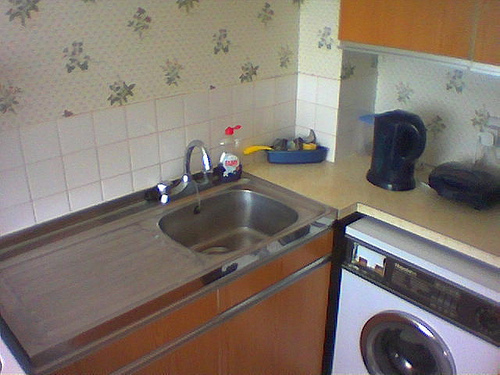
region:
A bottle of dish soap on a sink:
[220, 123, 243, 183]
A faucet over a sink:
[182, 138, 212, 177]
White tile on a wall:
[1, 72, 294, 237]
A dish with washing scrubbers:
[265, 140, 328, 161]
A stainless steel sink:
[149, 185, 314, 260]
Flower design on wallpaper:
[161, 57, 184, 89]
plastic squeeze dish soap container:
[218, 122, 241, 177]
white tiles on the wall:
[7, 72, 374, 237]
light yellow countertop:
[261, 144, 494, 263]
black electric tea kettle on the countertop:
[370, 106, 426, 189]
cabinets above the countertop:
[330, 2, 497, 66]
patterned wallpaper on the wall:
[4, 5, 499, 185]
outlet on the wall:
[467, 124, 497, 149]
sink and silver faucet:
[155, 141, 292, 251]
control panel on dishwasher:
[343, 239, 499, 335]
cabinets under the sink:
[33, 235, 343, 373]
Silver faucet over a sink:
[153, 135, 303, 261]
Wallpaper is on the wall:
[0, 0, 496, 175]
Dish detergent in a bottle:
[210, 120, 246, 185]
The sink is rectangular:
[150, 182, 300, 257]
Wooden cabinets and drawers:
[46, 220, 336, 370]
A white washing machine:
[321, 210, 496, 370]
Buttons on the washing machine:
[420, 281, 465, 321]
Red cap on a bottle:
[220, 117, 241, 137]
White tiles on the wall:
[0, 65, 382, 240]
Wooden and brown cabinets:
[331, 0, 496, 80]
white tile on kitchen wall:
[17, 118, 63, 164]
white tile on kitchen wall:
[53, 112, 97, 157]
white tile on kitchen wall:
[88, 103, 128, 148]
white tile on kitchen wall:
[122, 95, 155, 135]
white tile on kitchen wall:
[155, 93, 186, 133]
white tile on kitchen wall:
[23, 156, 65, 199]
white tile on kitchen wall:
[62, 146, 101, 188]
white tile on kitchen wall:
[95, 137, 130, 179]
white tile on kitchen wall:
[130, 130, 160, 173]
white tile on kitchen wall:
[157, 125, 187, 165]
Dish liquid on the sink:
[221, 119, 241, 186]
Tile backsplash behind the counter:
[0, 63, 382, 230]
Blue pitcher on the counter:
[366, 107, 427, 193]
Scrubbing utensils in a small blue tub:
[245, 129, 333, 167]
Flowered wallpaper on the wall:
[0, 0, 499, 184]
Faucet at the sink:
[156, 138, 221, 200]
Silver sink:
[161, 184, 327, 259]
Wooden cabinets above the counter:
[336, 0, 498, 67]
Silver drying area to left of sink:
[0, 215, 209, 357]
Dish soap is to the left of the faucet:
[207, 120, 256, 185]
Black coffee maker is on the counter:
[363, 105, 432, 195]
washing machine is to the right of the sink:
[327, 211, 499, 373]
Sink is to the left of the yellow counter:
[154, 183, 311, 263]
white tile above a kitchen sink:
[0, 70, 375, 237]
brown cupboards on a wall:
[335, 0, 497, 79]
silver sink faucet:
[151, 135, 219, 201]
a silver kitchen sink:
[1, 141, 336, 363]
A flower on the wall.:
[107, 76, 138, 99]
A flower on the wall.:
[55, 34, 90, 74]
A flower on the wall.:
[155, 56, 185, 93]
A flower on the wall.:
[209, 26, 231, 51]